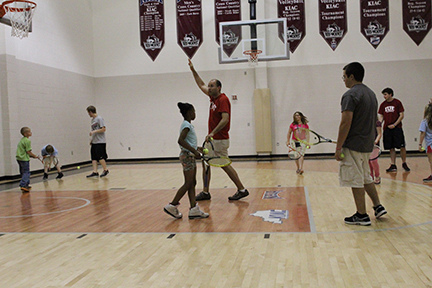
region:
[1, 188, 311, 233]
red colored square of wood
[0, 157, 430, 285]
court is made of wood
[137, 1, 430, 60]
championship banners hang above people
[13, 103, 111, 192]
three kids in group by wall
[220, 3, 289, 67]
basketball hoop is hung on black pole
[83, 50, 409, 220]
oldest people in group wearing shorts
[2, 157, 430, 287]
regular wood color of court is tan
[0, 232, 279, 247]
black tape lines by red square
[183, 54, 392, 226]
few people are holding tennis rackets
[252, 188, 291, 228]
sports logos in red wood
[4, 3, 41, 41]
white basketball goal netting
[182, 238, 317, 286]
wooden flooring on basketball court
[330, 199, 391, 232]
black and white tennis shoes on man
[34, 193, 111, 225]
white lines painted on basketball court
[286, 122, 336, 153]
yellow and black tennis racquet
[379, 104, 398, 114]
writing on front of shirt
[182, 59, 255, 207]
balding man holding hand up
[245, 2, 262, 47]
black metal pole securing basketball goal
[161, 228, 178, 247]
black line on basketball court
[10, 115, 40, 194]
young boy in green shirt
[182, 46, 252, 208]
a man with his hand raised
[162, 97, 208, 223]
a girl on a basketball court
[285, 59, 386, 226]
a man holding a tennis racket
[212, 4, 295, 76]
a basketball hoop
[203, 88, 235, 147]
man is wearing a red shirt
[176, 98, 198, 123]
girl has her hair in a bun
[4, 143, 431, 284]
a shiny wooden basketball court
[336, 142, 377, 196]
a man wearing khaki shorts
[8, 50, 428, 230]
A group of people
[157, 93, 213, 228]
A side view of a young girl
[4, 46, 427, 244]
People are on a basketball court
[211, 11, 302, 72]
A basketball hoop in the background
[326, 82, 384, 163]
Man is wearing a gray shirt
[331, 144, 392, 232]
Man is wearing shorts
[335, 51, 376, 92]
Man has short hair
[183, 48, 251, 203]
Man has his arm raise up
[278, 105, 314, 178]
Woman in the background is wearing a pink shirt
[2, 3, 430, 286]
Photo was taken indoors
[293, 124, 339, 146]
Tennis racket being used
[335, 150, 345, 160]
tennis ball in a guy's hands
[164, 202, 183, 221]
A white shoe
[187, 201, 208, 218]
A shoe on a foot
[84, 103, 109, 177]
A man playing sports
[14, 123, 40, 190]
A kid wearing a green shirt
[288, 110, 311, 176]
A girl wearing a pink shirt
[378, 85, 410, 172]
A guy wearing a dark red shirt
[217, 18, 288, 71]
Basketball hoop and backboard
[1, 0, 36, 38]
red basket hoop and net